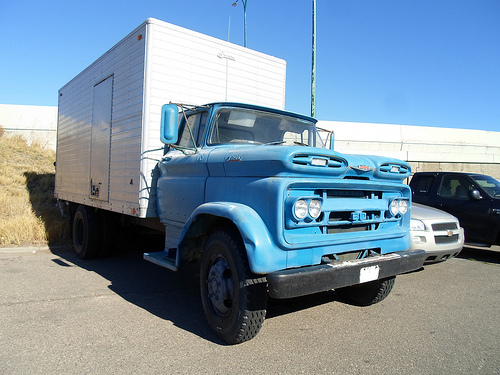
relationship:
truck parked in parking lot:
[50, 18, 426, 345] [9, 239, 499, 374]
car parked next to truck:
[404, 192, 471, 264] [50, 18, 426, 345]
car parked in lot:
[409, 200, 464, 265] [328, 310, 410, 354]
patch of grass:
[2, 142, 41, 218] [1, 131, 67, 243]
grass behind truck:
[1, 131, 67, 243] [50, 18, 426, 345]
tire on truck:
[199, 230, 269, 345] [50, 18, 426, 345]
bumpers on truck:
[272, 248, 427, 300] [34, 18, 478, 348]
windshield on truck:
[206, 106, 316, 146] [50, 18, 426, 345]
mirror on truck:
[156, 97, 184, 145] [50, 18, 426, 345]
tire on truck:
[201, 236, 247, 334] [46, 12, 398, 363]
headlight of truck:
[286, 194, 326, 224] [50, 18, 426, 345]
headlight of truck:
[387, 195, 411, 221] [50, 18, 426, 345]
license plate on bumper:
[360, 267, 380, 282] [274, 250, 426, 297]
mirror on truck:
[325, 127, 340, 150] [50, 18, 426, 345]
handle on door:
[157, 154, 174, 161] [149, 102, 216, 225]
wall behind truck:
[1, 99, 496, 195] [50, 18, 426, 345]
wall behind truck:
[1, 99, 496, 195] [407, 162, 493, 257]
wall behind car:
[1, 99, 496, 195] [408, 197, 465, 272]